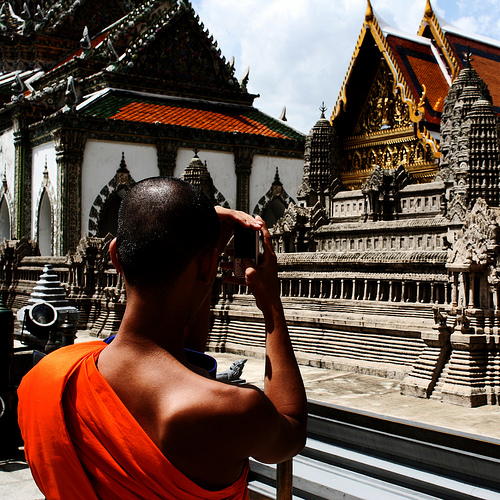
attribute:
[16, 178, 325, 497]
man — here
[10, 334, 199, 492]
toga — orange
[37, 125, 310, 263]
building — white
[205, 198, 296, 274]
camera — black, held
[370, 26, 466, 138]
trim — gold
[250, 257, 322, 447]
arm — bent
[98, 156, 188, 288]
hair — brown, short, here, black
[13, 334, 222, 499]
outfit — orange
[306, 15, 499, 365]
temple — painted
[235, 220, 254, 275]
phone — grey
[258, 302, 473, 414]
step — grey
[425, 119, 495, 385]
statue — grey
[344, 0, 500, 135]
roof — sloped, orange, painted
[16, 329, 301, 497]
clothing — worn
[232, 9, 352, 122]
sky — blue, here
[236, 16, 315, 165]
cloud — here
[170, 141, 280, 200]
wall — here, white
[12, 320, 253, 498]
wrap — orange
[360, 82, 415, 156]
design — gold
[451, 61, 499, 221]
pillar — stone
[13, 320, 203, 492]
tunic — orange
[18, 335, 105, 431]
shoulder — one